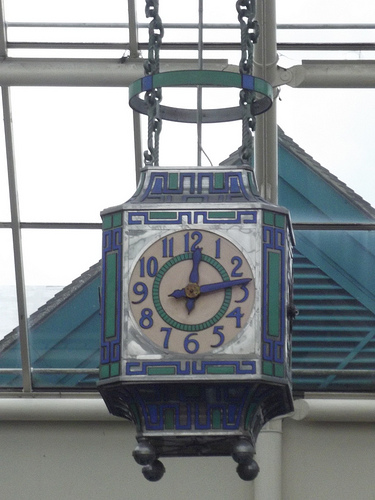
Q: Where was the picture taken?
A: In a building.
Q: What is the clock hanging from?
A: Chains.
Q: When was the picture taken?
A: 12:14.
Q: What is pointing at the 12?
A: Hour hand.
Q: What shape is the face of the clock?
A: Circle.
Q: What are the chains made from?
A: Metal.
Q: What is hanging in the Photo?
A: Clock.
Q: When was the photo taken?
A: Daytime.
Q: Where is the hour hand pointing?
A: Twelve.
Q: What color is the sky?
A: White.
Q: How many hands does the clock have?
A: Two.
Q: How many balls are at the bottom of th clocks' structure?
A: Four.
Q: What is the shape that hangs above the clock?
A: Circle.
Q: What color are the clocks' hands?
A: Blue.